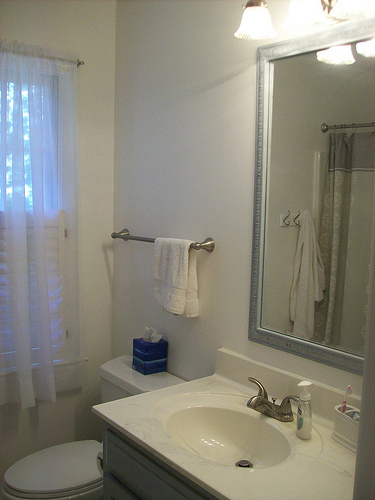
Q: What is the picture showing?
A: It is showing a bathroom.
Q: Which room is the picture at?
A: It is at the bathroom.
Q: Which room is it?
A: It is a bathroom.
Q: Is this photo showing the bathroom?
A: Yes, it is showing the bathroom.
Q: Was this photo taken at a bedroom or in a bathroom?
A: It was taken at a bathroom.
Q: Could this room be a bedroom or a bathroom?
A: It is a bathroom.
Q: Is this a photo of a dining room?
A: No, the picture is showing a bathroom.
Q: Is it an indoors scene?
A: Yes, it is indoors.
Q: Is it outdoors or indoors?
A: It is indoors.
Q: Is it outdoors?
A: No, it is indoors.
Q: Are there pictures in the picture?
A: No, there are no pictures.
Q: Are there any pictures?
A: No, there are no pictures.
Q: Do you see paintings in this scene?
A: No, there are no paintings.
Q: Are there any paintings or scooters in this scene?
A: No, there are no paintings or scooters.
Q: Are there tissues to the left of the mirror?
A: Yes, there is a tissue to the left of the mirror.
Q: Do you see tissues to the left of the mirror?
A: Yes, there is a tissue to the left of the mirror.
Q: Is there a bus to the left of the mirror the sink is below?
A: No, there is a tissue to the left of the mirror.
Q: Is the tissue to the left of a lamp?
A: No, the tissue is to the left of a mirror.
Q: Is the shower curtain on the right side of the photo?
A: Yes, the shower curtain is on the right of the image.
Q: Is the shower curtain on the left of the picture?
A: No, the shower curtain is on the right of the image.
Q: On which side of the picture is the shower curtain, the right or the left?
A: The shower curtain is on the right of the image.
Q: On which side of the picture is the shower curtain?
A: The shower curtain is on the right of the image.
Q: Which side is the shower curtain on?
A: The shower curtain is on the right of the image.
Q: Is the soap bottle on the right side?
A: Yes, the soap bottle is on the right of the image.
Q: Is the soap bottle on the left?
A: No, the soap bottle is on the right of the image.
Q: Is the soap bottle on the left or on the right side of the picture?
A: The soap bottle is on the right of the image.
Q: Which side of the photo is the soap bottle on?
A: The soap bottle is on the right of the image.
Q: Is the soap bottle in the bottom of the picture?
A: Yes, the soap bottle is in the bottom of the image.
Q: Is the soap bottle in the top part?
A: No, the soap bottle is in the bottom of the image.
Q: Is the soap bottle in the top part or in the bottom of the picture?
A: The soap bottle is in the bottom of the image.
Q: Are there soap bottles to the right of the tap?
A: Yes, there is a soap bottle to the right of the tap.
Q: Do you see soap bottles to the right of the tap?
A: Yes, there is a soap bottle to the right of the tap.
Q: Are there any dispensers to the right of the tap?
A: No, there is a soap bottle to the right of the tap.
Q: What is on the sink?
A: The soap bottle is on the sink.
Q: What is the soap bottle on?
A: The soap bottle is on the sink.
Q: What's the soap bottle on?
A: The soap bottle is on the sink.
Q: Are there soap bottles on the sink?
A: Yes, there is a soap bottle on the sink.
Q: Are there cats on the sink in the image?
A: No, there is a soap bottle on the sink.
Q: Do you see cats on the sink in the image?
A: No, there is a soap bottle on the sink.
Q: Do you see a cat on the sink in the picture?
A: No, there is a soap bottle on the sink.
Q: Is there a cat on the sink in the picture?
A: No, there is a soap bottle on the sink.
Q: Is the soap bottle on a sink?
A: Yes, the soap bottle is on a sink.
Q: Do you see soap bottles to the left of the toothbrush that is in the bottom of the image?
A: Yes, there is a soap bottle to the left of the toothbrush.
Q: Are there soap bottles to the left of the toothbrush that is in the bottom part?
A: Yes, there is a soap bottle to the left of the toothbrush.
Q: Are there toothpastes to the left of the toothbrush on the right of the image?
A: No, there is a soap bottle to the left of the toothbrush.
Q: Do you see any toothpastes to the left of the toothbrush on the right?
A: No, there is a soap bottle to the left of the toothbrush.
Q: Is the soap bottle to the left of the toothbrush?
A: Yes, the soap bottle is to the left of the toothbrush.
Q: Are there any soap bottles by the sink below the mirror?
A: Yes, there is a soap bottle by the sink.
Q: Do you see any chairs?
A: No, there are no chairs.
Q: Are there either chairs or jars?
A: No, there are no chairs or jars.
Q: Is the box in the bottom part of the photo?
A: Yes, the box is in the bottom of the image.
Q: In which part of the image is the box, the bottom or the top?
A: The box is in the bottom of the image.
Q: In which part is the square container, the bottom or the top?
A: The box is in the bottom of the image.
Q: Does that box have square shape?
A: Yes, the box is square.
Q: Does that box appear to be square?
A: Yes, the box is square.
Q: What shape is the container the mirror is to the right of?
A: The box is square.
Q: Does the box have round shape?
A: No, the box is square.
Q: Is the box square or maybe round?
A: The box is square.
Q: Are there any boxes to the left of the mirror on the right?
A: Yes, there is a box to the left of the mirror.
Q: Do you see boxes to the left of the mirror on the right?
A: Yes, there is a box to the left of the mirror.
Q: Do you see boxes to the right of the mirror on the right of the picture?
A: No, the box is to the left of the mirror.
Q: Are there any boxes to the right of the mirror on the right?
A: No, the box is to the left of the mirror.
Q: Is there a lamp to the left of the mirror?
A: No, there is a box to the left of the mirror.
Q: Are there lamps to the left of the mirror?
A: No, there is a box to the left of the mirror.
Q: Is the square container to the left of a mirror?
A: Yes, the box is to the left of a mirror.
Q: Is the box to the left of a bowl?
A: No, the box is to the left of a mirror.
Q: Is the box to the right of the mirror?
A: No, the box is to the left of the mirror.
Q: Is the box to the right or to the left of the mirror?
A: The box is to the left of the mirror.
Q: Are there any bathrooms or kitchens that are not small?
A: No, there is a bathroom but it is small.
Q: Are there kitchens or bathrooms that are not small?
A: No, there is a bathroom but it is small.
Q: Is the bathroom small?
A: Yes, the bathroom is small.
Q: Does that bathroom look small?
A: Yes, the bathroom is small.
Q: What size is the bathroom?
A: The bathroom is small.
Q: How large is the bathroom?
A: The bathroom is small.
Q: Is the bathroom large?
A: No, the bathroom is small.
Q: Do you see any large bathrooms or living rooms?
A: No, there is a bathroom but it is small.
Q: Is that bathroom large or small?
A: The bathroom is small.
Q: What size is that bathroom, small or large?
A: The bathroom is small.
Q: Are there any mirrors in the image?
A: Yes, there is a mirror.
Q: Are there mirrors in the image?
A: Yes, there is a mirror.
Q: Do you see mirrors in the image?
A: Yes, there is a mirror.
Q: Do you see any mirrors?
A: Yes, there is a mirror.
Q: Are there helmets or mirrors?
A: Yes, there is a mirror.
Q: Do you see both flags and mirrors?
A: No, there is a mirror but no flags.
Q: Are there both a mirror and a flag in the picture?
A: No, there is a mirror but no flags.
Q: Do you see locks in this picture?
A: No, there are no locks.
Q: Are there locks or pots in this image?
A: No, there are no locks or pots.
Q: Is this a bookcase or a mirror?
A: This is a mirror.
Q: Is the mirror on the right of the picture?
A: Yes, the mirror is on the right of the image.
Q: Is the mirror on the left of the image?
A: No, the mirror is on the right of the image.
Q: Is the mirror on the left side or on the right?
A: The mirror is on the right of the image.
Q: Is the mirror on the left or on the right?
A: The mirror is on the right of the image.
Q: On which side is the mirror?
A: The mirror is on the right of the image.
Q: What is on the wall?
A: The mirror is on the wall.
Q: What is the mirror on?
A: The mirror is on the wall.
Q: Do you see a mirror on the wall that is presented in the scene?
A: Yes, there is a mirror on the wall.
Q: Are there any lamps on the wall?
A: No, there is a mirror on the wall.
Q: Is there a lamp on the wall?
A: No, there is a mirror on the wall.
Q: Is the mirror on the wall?
A: Yes, the mirror is on the wall.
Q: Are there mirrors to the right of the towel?
A: Yes, there is a mirror to the right of the towel.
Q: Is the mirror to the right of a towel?
A: Yes, the mirror is to the right of a towel.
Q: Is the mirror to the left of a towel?
A: No, the mirror is to the right of a towel.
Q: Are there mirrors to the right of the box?
A: Yes, there is a mirror to the right of the box.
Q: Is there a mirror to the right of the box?
A: Yes, there is a mirror to the right of the box.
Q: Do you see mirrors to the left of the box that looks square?
A: No, the mirror is to the right of the box.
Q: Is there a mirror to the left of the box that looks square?
A: No, the mirror is to the right of the box.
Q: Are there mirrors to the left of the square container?
A: No, the mirror is to the right of the box.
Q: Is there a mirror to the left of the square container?
A: No, the mirror is to the right of the box.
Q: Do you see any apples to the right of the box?
A: No, there is a mirror to the right of the box.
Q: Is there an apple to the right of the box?
A: No, there is a mirror to the right of the box.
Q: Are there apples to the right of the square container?
A: No, there is a mirror to the right of the box.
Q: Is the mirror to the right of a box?
A: Yes, the mirror is to the right of a box.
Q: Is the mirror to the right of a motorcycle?
A: No, the mirror is to the right of a box.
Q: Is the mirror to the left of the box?
A: No, the mirror is to the right of the box.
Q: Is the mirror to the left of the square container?
A: No, the mirror is to the right of the box.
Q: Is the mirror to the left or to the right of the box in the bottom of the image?
A: The mirror is to the right of the box.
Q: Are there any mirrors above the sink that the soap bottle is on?
A: Yes, there is a mirror above the sink.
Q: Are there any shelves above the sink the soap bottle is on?
A: No, there is a mirror above the sink.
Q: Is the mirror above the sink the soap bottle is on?
A: Yes, the mirror is above the sink.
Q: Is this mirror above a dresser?
A: No, the mirror is above the sink.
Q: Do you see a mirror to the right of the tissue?
A: Yes, there is a mirror to the right of the tissue.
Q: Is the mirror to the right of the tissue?
A: Yes, the mirror is to the right of the tissue.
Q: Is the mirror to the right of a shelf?
A: No, the mirror is to the right of the tissue.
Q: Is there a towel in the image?
A: Yes, there is a towel.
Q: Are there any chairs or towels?
A: Yes, there is a towel.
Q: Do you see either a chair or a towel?
A: Yes, there is a towel.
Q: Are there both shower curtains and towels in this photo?
A: Yes, there are both a towel and a shower curtain.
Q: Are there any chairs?
A: No, there are no chairs.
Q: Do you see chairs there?
A: No, there are no chairs.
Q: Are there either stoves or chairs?
A: No, there are no chairs or stoves.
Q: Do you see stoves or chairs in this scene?
A: No, there are no chairs or stoves.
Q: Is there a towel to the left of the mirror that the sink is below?
A: Yes, there is a towel to the left of the mirror.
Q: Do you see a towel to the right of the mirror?
A: No, the towel is to the left of the mirror.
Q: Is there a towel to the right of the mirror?
A: No, the towel is to the left of the mirror.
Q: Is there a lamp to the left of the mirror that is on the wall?
A: No, there is a towel to the left of the mirror.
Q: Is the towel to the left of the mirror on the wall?
A: Yes, the towel is to the left of the mirror.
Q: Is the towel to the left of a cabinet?
A: No, the towel is to the left of the mirror.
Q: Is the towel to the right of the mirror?
A: No, the towel is to the left of the mirror.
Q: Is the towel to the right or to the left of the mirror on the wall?
A: The towel is to the left of the mirror.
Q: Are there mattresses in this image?
A: No, there are no mattresses.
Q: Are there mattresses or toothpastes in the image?
A: No, there are no mattresses or toothpastes.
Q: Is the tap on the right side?
A: Yes, the tap is on the right of the image.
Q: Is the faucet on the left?
A: No, the faucet is on the right of the image.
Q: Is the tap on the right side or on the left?
A: The tap is on the right of the image.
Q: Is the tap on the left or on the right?
A: The tap is on the right of the image.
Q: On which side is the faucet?
A: The faucet is on the right of the image.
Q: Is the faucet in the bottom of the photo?
A: Yes, the faucet is in the bottom of the image.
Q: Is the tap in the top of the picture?
A: No, the tap is in the bottom of the image.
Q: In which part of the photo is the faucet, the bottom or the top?
A: The faucet is in the bottom of the image.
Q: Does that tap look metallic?
A: Yes, the tap is metallic.